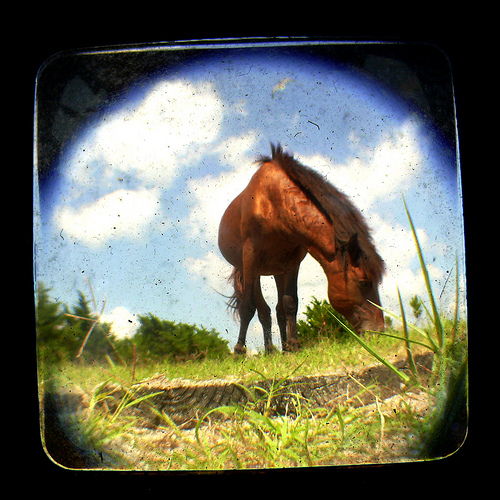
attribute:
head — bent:
[325, 247, 382, 336]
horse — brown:
[217, 153, 382, 340]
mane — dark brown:
[267, 144, 394, 286]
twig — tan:
[57, 243, 147, 354]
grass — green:
[46, 322, 457, 462]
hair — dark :
[273, 147, 348, 203]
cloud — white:
[78, 79, 225, 225]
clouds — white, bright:
[111, 95, 216, 182]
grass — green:
[42, 340, 458, 460]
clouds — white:
[98, 80, 224, 180]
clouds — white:
[217, 132, 247, 163]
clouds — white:
[51, 180, 175, 247]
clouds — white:
[59, 135, 98, 187]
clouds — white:
[321, 125, 436, 201]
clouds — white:
[370, 210, 445, 302]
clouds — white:
[192, 240, 234, 289]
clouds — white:
[187, 162, 243, 218]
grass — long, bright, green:
[88, 359, 422, 460]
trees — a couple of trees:
[73, 316, 194, 355]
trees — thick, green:
[104, 304, 288, 376]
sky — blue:
[157, 68, 377, 143]